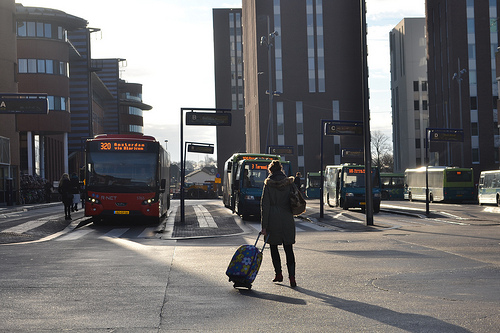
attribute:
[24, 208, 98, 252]
lines — white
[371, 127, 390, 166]
tree — tall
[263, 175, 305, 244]
coat — long, green, woman's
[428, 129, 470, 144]
sign — tall, black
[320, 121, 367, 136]
sign — tall, black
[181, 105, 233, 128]
sign — tall, black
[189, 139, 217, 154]
sign — tall, black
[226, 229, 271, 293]
suitcase — colorful flower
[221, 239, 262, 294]
suitcase — floral 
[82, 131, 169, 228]
bus — city, red, yellow and blue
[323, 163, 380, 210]
bus — yellow and blue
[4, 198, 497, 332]
road — paved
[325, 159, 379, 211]
bus — red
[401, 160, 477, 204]
bus — red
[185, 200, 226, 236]
lines — double, white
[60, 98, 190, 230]
bus — small, blue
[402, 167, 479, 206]
bus — yellow and blue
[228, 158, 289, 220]
bus — yellow and blue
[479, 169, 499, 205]
bus — yellow and blue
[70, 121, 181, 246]
bus — red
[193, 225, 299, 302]
luggage — flowered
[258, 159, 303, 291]
passenger — bus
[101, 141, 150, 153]
lights — orange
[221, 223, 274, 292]
floral suitcase — floral 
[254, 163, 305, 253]
coat — fur lined